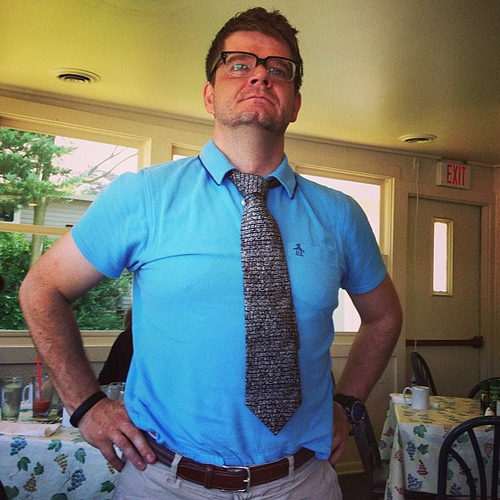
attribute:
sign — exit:
[434, 159, 472, 189]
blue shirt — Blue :
[90, 156, 363, 454]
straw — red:
[29, 352, 49, 379]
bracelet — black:
[67, 388, 102, 424]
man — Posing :
[195, 6, 363, 289]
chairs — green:
[335, 345, 498, 495]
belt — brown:
[141, 431, 316, 493]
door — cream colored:
[404, 189, 485, 453]